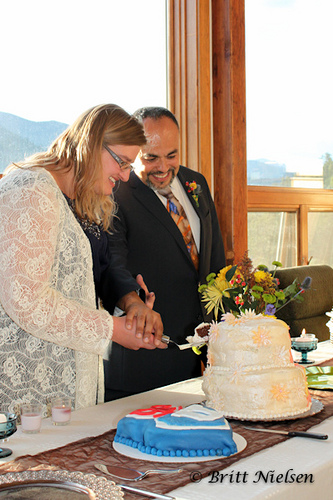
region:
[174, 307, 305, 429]
The couple is cutting the cake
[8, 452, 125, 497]
There is an empty platter here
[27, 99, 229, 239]
The couple is smiling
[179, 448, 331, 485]
This was taken by Britt Neilsen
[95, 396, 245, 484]
This cake is blue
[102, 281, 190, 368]
Both people are holding the knife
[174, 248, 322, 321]
There are flowers behind the cake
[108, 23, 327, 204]
The weather is clear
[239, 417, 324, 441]
There is another knife on the table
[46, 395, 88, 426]
This candle is lit up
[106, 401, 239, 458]
Red, white, and blue cake on the table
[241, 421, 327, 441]
Knife on the table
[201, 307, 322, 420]
White floral wedding cake on the table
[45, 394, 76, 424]
Lit pink and white candle on the table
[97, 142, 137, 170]
Gray glasses over the woman's eyes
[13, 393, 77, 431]
Two pink and white candles on the table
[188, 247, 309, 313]
Multi-color floral arrangements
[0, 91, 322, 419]
Man and woman cutting the cake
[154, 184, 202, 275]
Brown, blue, and orange tie around the man's neck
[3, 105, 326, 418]
A couple cutting a white floral cake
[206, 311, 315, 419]
White flowery wedding cake.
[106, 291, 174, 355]
Wedding couple's hands holding the cake cutter.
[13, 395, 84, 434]
Small white candles on table.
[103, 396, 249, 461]
Blue, white and red cake on white plate.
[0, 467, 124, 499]
Silver platter in left hand corner.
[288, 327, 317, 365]
Lit candle in blue glass on table.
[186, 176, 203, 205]
Flowers on the man's black suit jacket.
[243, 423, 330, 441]
Knife with black handle on the table next to the wedding cake.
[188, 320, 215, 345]
Cut piece of the wedding cake.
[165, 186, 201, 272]
The man's colorful necktie.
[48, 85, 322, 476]
The man and woman are cutting the cake.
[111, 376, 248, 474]
The cake is blue.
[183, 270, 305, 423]
The cakes is white.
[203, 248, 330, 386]
There are flowers on the table.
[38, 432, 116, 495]
There runner on the table is burgundy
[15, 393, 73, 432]
There are candles on the table.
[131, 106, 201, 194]
The man is smiling.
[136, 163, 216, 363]
The man is wearing a black suit.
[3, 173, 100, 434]
The woman is wearing a white jacket.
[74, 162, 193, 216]
The woman is smiling.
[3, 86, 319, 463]
two people are cutting a cake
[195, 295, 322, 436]
the cake is white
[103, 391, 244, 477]
one of the cakes is blue, red and white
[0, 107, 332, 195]
behind the people are mountains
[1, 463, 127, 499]
a silver plate sits on the table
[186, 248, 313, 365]
the flowers are colorful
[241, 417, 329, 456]
a knife is on the table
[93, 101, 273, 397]
the man is wearing a tie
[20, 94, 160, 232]
the woman is wearing glasses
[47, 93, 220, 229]
the people are smiling